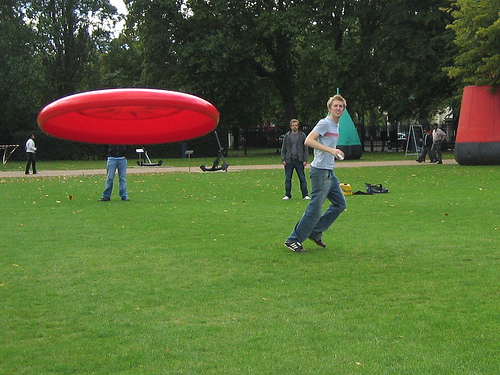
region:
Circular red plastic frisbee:
[39, 87, 219, 147]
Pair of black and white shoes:
[285, 237, 326, 253]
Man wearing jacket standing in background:
[278, 118, 308, 203]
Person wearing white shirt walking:
[25, 131, 40, 173]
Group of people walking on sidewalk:
[419, 122, 445, 162]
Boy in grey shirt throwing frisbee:
[286, 95, 346, 255]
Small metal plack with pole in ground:
[182, 146, 195, 172]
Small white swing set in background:
[404, 122, 426, 157]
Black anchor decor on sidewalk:
[200, 131, 230, 173]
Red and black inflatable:
[451, 84, 498, 164]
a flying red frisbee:
[36, 87, 222, 146]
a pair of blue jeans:
[289, 167, 349, 242]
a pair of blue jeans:
[101, 156, 130, 198]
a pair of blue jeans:
[282, 155, 308, 196]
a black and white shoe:
[285, 239, 303, 252]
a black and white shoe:
[310, 237, 325, 249]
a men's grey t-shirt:
[312, 117, 339, 168]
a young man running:
[284, 94, 352, 256]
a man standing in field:
[278, 117, 314, 201]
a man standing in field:
[94, 146, 136, 204]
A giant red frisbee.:
[36, 84, 226, 154]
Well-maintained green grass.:
[43, 235, 169, 336]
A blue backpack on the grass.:
[352, 165, 404, 201]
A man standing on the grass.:
[279, 116, 309, 203]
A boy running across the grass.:
[284, 93, 351, 255]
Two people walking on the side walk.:
[417, 119, 446, 165]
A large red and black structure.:
[454, 83, 499, 164]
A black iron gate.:
[361, 124, 403, 149]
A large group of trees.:
[152, 9, 432, 86]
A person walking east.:
[20, 133, 41, 178]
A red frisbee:
[34, 83, 223, 148]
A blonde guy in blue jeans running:
[281, 93, 356, 254]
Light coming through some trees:
[1, 0, 183, 40]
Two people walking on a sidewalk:
[401, 119, 450, 164]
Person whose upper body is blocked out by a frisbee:
[33, 86, 227, 205]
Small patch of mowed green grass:
[69, 250, 176, 304]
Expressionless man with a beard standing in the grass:
[271, 115, 312, 203]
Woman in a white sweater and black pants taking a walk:
[17, 125, 42, 179]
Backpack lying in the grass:
[353, 171, 403, 207]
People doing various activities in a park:
[13, 92, 450, 267]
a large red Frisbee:
[26, 78, 226, 156]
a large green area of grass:
[0, 159, 498, 374]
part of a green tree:
[432, 0, 498, 85]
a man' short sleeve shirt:
[309, 115, 346, 173]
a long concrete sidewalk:
[0, 149, 460, 181]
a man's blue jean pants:
[292, 157, 348, 238]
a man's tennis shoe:
[287, 235, 305, 254]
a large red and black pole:
[453, 71, 498, 165]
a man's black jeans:
[23, 150, 38, 170]